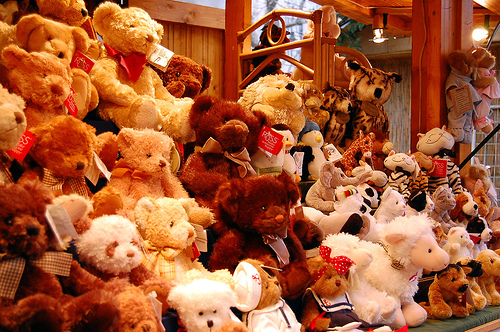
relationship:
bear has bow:
[300, 246, 391, 332] [316, 245, 350, 279]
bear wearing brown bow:
[0, 170, 120, 332] [113, 157, 152, 184]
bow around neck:
[0, 251, 72, 299] [3, 232, 70, 290]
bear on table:
[203, 166, 318, 294] [403, 295, 497, 329]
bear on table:
[339, 59, 403, 147] [403, 287, 493, 330]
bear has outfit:
[452, 44, 498, 106] [470, 69, 493, 130]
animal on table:
[417, 125, 470, 197] [404, 300, 492, 330]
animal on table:
[166, 279, 250, 332] [409, 300, 499, 330]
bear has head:
[304, 250, 368, 325] [310, 260, 344, 302]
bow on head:
[313, 237, 356, 275] [310, 260, 344, 302]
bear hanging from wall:
[467, 46, 500, 134] [409, 4, 486, 156]